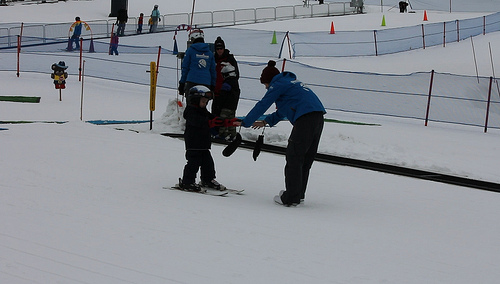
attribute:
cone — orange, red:
[324, 19, 338, 35]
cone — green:
[376, 13, 390, 30]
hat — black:
[259, 56, 282, 81]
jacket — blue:
[175, 44, 225, 84]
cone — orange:
[420, 7, 433, 21]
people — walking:
[114, 6, 171, 39]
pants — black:
[181, 147, 219, 186]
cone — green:
[267, 27, 284, 46]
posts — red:
[76, 38, 89, 79]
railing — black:
[321, 151, 498, 198]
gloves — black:
[221, 130, 266, 162]